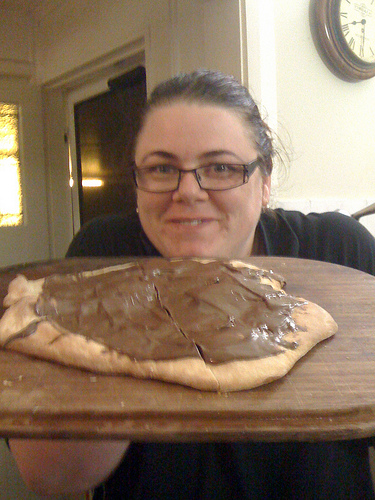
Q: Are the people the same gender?
A: Yes, all the people are female.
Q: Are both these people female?
A: Yes, all the people are female.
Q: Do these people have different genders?
A: No, all the people are female.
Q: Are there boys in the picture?
A: No, there are no boys.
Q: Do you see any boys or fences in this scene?
A: No, there are no boys or fences.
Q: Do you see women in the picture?
A: Yes, there is a woman.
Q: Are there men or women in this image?
A: Yes, there is a woman.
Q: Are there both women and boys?
A: No, there is a woman but no boys.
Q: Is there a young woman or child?
A: Yes, there is a young woman.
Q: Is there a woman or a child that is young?
A: Yes, the woman is young.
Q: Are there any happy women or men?
A: Yes, there is a happy woman.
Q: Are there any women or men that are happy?
A: Yes, the woman is happy.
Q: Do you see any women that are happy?
A: Yes, there is a happy woman.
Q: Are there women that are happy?
A: Yes, there is a woman that is happy.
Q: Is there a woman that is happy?
A: Yes, there is a woman that is happy.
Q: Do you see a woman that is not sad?
A: Yes, there is a happy woman.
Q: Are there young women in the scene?
A: Yes, there is a young woman.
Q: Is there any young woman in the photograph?
A: Yes, there is a young woman.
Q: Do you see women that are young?
A: Yes, there is a young woman.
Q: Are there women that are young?
A: Yes, there is a woman that is young.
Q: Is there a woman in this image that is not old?
A: Yes, there is an young woman.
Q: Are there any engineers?
A: No, there are no engineers.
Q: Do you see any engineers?
A: No, there are no engineers.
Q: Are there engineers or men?
A: No, there are no engineers or men.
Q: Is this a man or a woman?
A: This is a woman.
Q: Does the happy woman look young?
A: Yes, the woman is young.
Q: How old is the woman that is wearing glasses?
A: The woman is young.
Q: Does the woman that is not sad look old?
A: No, the woman is young.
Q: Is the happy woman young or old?
A: The woman is young.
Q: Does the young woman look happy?
A: Yes, the woman is happy.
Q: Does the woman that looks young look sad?
A: No, the woman is happy.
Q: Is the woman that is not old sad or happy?
A: The woman is happy.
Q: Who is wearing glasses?
A: The woman is wearing glasses.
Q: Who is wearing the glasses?
A: The woman is wearing glasses.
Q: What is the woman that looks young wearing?
A: The woman is wearing glasses.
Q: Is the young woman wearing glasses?
A: Yes, the woman is wearing glasses.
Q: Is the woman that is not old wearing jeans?
A: No, the woman is wearing glasses.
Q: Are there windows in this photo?
A: Yes, there is a window.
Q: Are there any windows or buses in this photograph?
A: Yes, there is a window.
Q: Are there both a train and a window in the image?
A: No, there is a window but no trains.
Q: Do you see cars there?
A: No, there are no cars.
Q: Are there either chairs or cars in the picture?
A: No, there are no cars or chairs.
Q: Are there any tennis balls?
A: No, there are no tennis balls.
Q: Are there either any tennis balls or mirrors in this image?
A: No, there are no tennis balls or mirrors.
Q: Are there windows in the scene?
A: Yes, there is a window.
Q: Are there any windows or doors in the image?
A: Yes, there is a window.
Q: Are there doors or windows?
A: Yes, there is a window.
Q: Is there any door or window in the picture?
A: Yes, there is a window.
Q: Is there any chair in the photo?
A: No, there are no chairs.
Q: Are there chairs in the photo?
A: No, there are no chairs.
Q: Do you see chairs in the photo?
A: No, there are no chairs.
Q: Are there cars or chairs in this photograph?
A: No, there are no chairs or cars.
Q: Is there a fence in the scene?
A: No, there are no fences.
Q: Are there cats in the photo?
A: No, there are no cats.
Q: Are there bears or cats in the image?
A: No, there are no cats or bears.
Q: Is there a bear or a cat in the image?
A: No, there are no cats or bears.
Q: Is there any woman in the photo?
A: Yes, there is a woman.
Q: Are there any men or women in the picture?
A: Yes, there is a woman.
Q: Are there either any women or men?
A: Yes, there is a woman.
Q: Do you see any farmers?
A: No, there are no farmers.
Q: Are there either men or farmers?
A: No, there are no farmers or men.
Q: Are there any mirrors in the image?
A: No, there are no mirrors.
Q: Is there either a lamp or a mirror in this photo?
A: No, there are no mirrors or lamps.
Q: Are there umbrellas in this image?
A: No, there are no umbrellas.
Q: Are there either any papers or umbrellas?
A: No, there are no umbrellas or papers.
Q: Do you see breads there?
A: Yes, there is a bread.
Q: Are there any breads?
A: Yes, there is a bread.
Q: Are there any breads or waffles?
A: Yes, there is a bread.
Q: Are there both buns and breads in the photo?
A: No, there is a bread but no buns.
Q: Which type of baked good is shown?
A: The baked good is a bread.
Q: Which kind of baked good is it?
A: The food is a bread.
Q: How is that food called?
A: This is a bread.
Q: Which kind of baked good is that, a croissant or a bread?
A: This is a bread.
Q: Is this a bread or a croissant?
A: This is a bread.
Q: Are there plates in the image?
A: Yes, there is a plate.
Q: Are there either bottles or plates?
A: Yes, there is a plate.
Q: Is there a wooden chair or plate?
A: Yes, there is a wood plate.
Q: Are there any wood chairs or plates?
A: Yes, there is a wood plate.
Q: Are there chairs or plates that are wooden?
A: Yes, the plate is wooden.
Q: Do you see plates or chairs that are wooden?
A: Yes, the plate is wooden.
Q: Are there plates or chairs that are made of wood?
A: Yes, the plate is made of wood.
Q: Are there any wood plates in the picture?
A: Yes, there is a wood plate.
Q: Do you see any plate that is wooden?
A: Yes, there is a wood plate.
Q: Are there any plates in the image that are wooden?
A: Yes, there is a plate that is wooden.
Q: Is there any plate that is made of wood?
A: Yes, there is a plate that is made of wood.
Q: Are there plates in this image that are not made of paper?
A: Yes, there is a plate that is made of wood.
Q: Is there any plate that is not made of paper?
A: Yes, there is a plate that is made of wood.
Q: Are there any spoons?
A: No, there are no spoons.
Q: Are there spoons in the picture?
A: No, there are no spoons.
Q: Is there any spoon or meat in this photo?
A: No, there are no spoons or meat.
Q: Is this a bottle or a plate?
A: This is a plate.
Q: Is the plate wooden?
A: Yes, the plate is wooden.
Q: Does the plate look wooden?
A: Yes, the plate is wooden.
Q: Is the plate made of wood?
A: Yes, the plate is made of wood.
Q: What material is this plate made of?
A: The plate is made of wood.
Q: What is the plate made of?
A: The plate is made of wood.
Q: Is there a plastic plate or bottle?
A: No, there is a plate but it is wooden.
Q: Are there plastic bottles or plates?
A: No, there is a plate but it is wooden.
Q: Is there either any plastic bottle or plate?
A: No, there is a plate but it is wooden.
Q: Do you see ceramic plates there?
A: No, there is a plate but it is wooden.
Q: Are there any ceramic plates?
A: No, there is a plate but it is wooden.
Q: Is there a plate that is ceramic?
A: No, there is a plate but it is wooden.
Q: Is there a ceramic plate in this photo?
A: No, there is a plate but it is wooden.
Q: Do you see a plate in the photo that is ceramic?
A: No, there is a plate but it is wooden.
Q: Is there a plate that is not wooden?
A: No, there is a plate but it is wooden.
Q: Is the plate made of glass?
A: No, the plate is made of wood.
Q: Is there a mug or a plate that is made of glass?
A: No, there is a plate but it is made of wood.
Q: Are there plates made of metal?
A: No, there is a plate but it is made of wood.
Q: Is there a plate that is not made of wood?
A: No, there is a plate but it is made of wood.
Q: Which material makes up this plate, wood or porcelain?
A: The plate is made of wood.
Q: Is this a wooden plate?
A: Yes, this is a wooden plate.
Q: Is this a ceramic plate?
A: No, this is a wooden plate.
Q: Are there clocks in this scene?
A: Yes, there is a clock.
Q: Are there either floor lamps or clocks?
A: Yes, there is a clock.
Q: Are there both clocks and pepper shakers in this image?
A: No, there is a clock but no pepper shakers.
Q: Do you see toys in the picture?
A: No, there are no toys.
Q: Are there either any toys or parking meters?
A: No, there are no toys or parking meters.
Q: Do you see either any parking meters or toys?
A: No, there are no toys or parking meters.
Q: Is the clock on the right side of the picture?
A: Yes, the clock is on the right of the image.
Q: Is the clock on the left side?
A: No, the clock is on the right of the image.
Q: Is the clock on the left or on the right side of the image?
A: The clock is on the right of the image.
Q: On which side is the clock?
A: The clock is on the right of the image.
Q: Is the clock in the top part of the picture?
A: Yes, the clock is in the top of the image.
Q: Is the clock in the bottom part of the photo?
A: No, the clock is in the top of the image.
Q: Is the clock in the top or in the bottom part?
A: The clock is in the top of the image.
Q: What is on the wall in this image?
A: The clock is on the wall.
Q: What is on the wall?
A: The clock is on the wall.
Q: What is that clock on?
A: The clock is on the wall.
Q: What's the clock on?
A: The clock is on the wall.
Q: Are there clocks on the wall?
A: Yes, there is a clock on the wall.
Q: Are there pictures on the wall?
A: No, there is a clock on the wall.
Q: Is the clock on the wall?
A: Yes, the clock is on the wall.